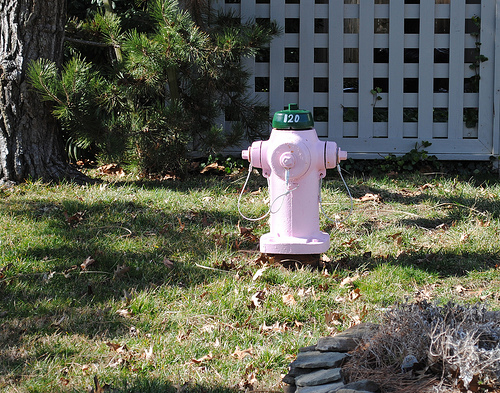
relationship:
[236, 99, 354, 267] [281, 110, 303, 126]
fire hydrant number 120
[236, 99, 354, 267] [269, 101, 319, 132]
fire hydrant has green top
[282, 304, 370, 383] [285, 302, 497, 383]
rocks laid out in circular pattern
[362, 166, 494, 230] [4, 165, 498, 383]
shadow cast on ground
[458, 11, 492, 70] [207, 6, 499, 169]
plants coming through fence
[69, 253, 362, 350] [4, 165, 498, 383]
leaves scattered in grass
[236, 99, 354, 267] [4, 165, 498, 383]
fire hydrant in grass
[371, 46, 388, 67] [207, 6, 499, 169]
space in fence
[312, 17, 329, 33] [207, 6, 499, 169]
space in fence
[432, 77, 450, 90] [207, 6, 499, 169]
space in fence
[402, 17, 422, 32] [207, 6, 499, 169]
space in fence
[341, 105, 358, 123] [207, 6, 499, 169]
space in fence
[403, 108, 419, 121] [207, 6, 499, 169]
space in fence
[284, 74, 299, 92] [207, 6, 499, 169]
space in fence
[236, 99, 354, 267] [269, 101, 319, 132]
fire hydrant has green cap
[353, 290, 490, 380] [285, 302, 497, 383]
flower in a dead garden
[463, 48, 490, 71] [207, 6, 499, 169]
weed growing by fence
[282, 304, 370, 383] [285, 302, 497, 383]
stone in a enclosure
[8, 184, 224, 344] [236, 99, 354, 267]
shadow near fire hydrant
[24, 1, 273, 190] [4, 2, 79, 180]
bush near a tree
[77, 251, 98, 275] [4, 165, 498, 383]
leaf on grass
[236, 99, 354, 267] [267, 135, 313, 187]
fire hydrant has a valve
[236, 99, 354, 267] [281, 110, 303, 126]
fire hydrant written 120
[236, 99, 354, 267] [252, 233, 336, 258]
fire hydrant has pink base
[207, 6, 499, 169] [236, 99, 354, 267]
fence behind hydrant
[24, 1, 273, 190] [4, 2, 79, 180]
bush at base of tree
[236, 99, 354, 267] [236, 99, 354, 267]
wall near hydrant